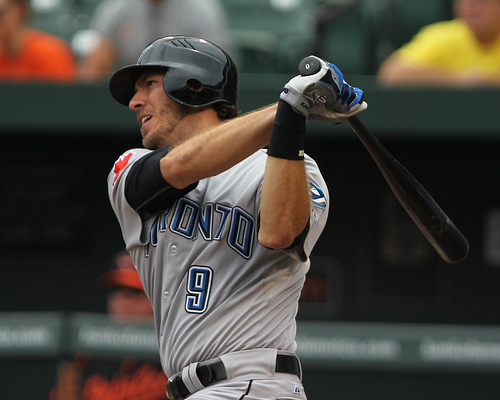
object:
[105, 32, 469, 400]
man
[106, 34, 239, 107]
helmet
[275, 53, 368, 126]
glove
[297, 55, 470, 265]
bat